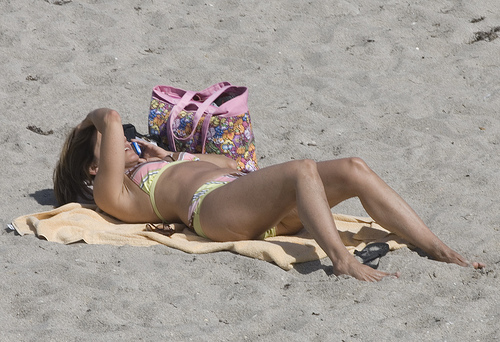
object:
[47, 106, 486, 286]
lady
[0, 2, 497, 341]
beach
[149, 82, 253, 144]
purse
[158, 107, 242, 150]
design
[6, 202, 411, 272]
blanket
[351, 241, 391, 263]
sandal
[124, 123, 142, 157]
phone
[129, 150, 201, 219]
bathing suit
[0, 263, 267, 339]
sand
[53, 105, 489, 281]
woman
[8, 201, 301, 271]
towel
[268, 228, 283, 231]
vagina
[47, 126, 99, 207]
hair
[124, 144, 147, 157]
cellphone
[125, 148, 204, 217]
clothing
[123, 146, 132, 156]
mouth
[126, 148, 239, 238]
bikini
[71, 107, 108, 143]
hand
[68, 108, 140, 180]
head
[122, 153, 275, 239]
body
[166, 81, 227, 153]
handles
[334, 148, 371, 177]
knees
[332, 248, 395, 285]
foot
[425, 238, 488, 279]
foot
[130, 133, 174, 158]
hand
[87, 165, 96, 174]
ear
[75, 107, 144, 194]
arm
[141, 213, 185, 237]
sunglasses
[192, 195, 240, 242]
hip